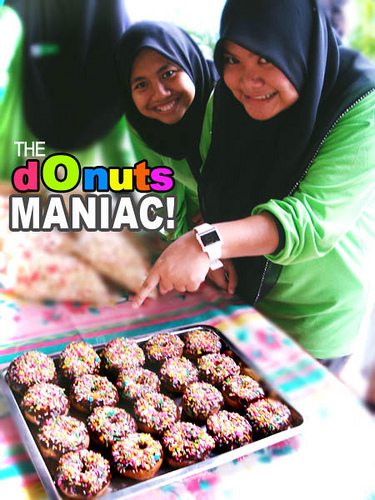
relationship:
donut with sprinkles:
[7, 330, 293, 499] [47, 424, 78, 442]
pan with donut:
[1, 324, 304, 499] [182, 327, 222, 355]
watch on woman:
[193, 222, 224, 271] [132, 0, 374, 396]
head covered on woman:
[209, 1, 335, 136] [106, 14, 319, 392]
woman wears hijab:
[132, 0, 374, 395] [243, 17, 366, 182]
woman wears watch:
[132, 0, 374, 396] [190, 220, 230, 275]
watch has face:
[191, 218, 225, 271] [197, 225, 221, 251]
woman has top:
[132, 0, 374, 396] [212, 101, 368, 320]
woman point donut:
[132, 0, 374, 395] [7, 330, 293, 499]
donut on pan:
[7, 330, 293, 499] [1, 324, 309, 499]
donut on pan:
[242, 395, 293, 430] [1, 324, 309, 499]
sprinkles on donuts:
[36, 356, 250, 437] [3, 325, 293, 496]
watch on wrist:
[193, 222, 224, 271] [186, 220, 233, 269]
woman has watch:
[132, 0, 374, 396] [193, 222, 224, 271]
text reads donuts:
[7, 146, 178, 197] [39, 320, 210, 434]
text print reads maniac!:
[6, 193, 184, 232] [5, 190, 182, 237]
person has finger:
[0, 2, 149, 281] [128, 271, 160, 309]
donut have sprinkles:
[7, 330, 293, 499] [138, 394, 171, 425]